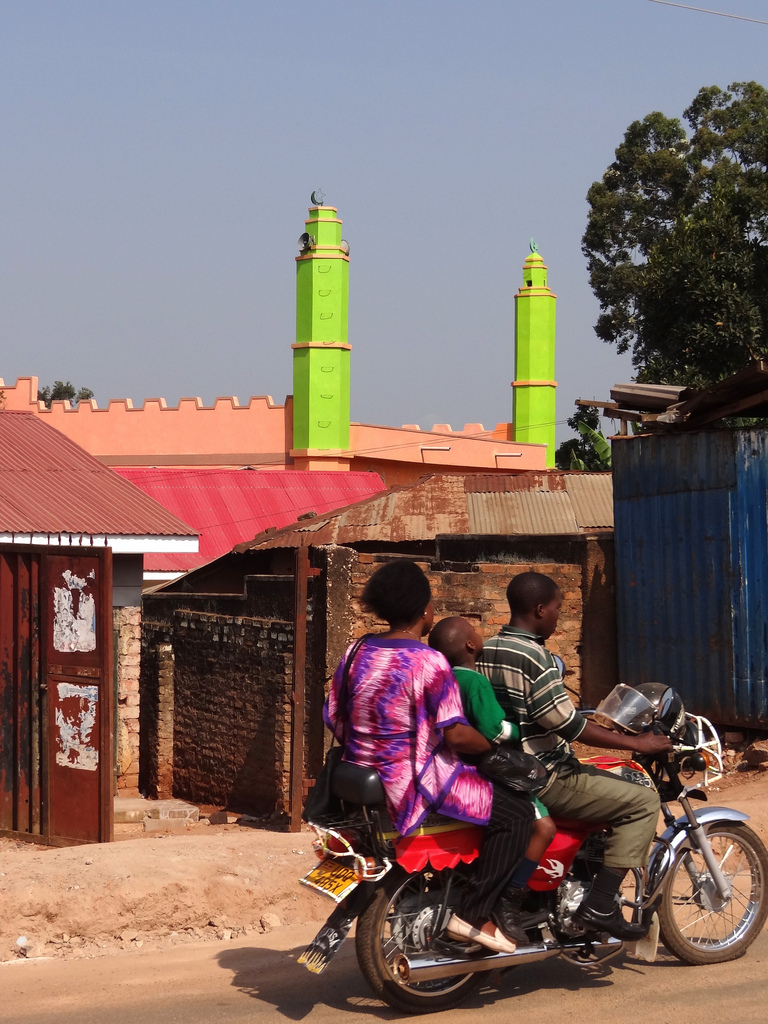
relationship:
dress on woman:
[325, 635, 495, 843] [327, 558, 535, 959]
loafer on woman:
[443, 906, 517, 955] [327, 558, 535, 959]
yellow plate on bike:
[294, 853, 362, 901] [300, 681, 762, 1009]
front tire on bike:
[653, 808, 768, 964] [300, 680, 764, 965]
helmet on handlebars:
[589, 675, 681, 738] [575, 702, 720, 772]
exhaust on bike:
[393, 924, 625, 986] [300, 681, 762, 1009]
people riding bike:
[333, 559, 650, 950] [300, 681, 768, 1012]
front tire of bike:
[646, 808, 765, 964] [300, 681, 762, 1009]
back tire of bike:
[353, 867, 489, 1008] [300, 681, 762, 1009]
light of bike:
[310, 820, 379, 886] [345, 678, 766, 1014]